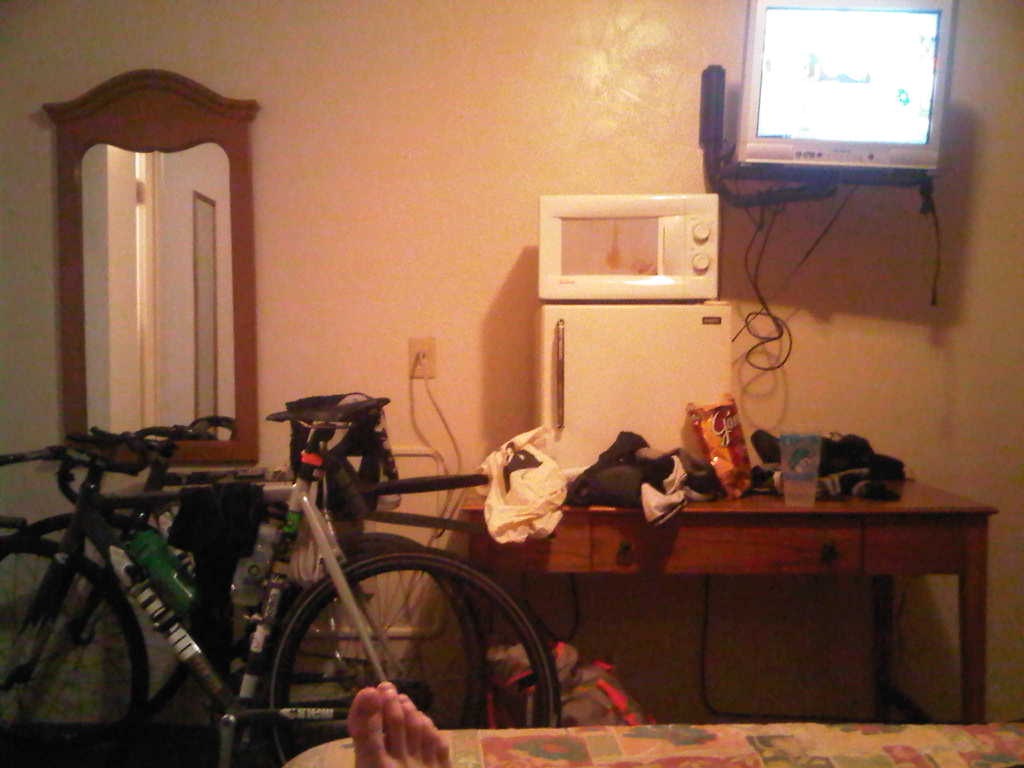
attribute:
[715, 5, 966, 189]
television — silver, wall mounted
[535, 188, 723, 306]
microwave — white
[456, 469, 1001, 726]
table — brown, wood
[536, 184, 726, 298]
microwave — white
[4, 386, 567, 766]
bike — indoors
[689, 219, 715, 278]
dials — round